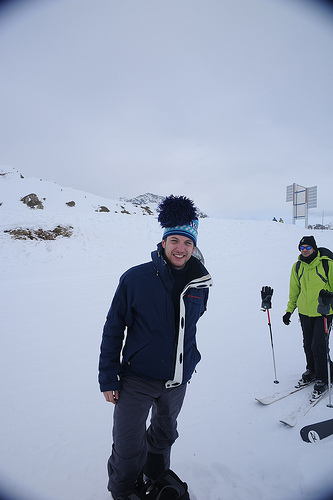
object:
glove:
[260, 284, 276, 310]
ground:
[0, 146, 332, 499]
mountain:
[123, 193, 208, 217]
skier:
[281, 234, 332, 399]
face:
[297, 243, 315, 259]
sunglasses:
[298, 243, 313, 252]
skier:
[96, 188, 214, 498]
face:
[166, 234, 194, 267]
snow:
[1, 169, 332, 498]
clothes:
[96, 241, 216, 500]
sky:
[1, 0, 330, 213]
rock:
[22, 193, 41, 209]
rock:
[62, 198, 76, 208]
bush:
[5, 222, 75, 243]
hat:
[155, 191, 201, 247]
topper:
[157, 193, 198, 226]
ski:
[254, 375, 332, 444]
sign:
[284, 181, 317, 228]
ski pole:
[265, 307, 280, 386]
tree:
[278, 216, 285, 223]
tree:
[272, 215, 277, 222]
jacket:
[97, 241, 215, 400]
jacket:
[284, 246, 332, 319]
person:
[94, 182, 213, 497]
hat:
[297, 230, 318, 258]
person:
[283, 235, 332, 396]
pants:
[107, 373, 186, 498]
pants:
[298, 312, 331, 397]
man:
[97, 189, 215, 500]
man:
[282, 234, 332, 394]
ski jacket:
[95, 242, 218, 396]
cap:
[157, 194, 200, 247]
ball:
[157, 192, 198, 230]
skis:
[254, 383, 332, 453]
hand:
[101, 390, 119, 406]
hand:
[281, 310, 293, 326]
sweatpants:
[107, 375, 186, 499]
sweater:
[285, 246, 333, 320]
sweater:
[97, 243, 214, 399]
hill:
[1, 168, 332, 499]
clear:
[66, 149, 134, 177]